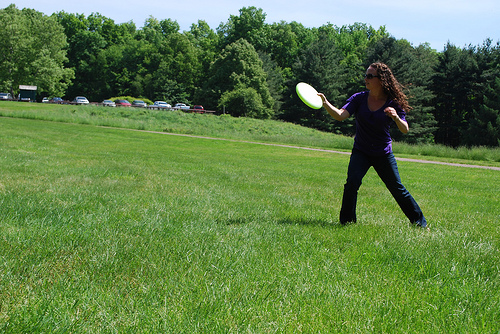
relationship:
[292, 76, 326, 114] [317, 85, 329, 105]
frisbee on hand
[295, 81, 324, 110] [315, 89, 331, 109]
frisbee on hand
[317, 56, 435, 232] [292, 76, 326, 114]
girl plays frisbee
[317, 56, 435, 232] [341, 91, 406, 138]
girl wears shirt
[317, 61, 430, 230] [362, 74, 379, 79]
girl wears glasses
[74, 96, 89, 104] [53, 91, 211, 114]
car in lot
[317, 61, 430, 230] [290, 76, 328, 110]
girl holds frisbee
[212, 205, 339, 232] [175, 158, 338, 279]
shadow on grass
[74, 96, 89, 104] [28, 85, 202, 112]
car in parking lot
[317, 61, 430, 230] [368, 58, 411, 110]
girl has hair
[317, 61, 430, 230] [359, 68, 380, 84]
girl has sunglasses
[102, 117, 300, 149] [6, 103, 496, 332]
pathway in park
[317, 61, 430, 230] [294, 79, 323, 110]
girl playing frisbee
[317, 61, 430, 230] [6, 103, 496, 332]
girl in park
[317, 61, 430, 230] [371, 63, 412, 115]
girl has hair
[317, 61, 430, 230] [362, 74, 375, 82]
girl wearing glasses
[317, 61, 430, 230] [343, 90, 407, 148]
girl has on shirt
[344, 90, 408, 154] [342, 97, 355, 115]
shirt has short sleeve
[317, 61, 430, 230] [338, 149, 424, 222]
girl has on pants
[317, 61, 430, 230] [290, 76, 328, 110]
girl holding frisbee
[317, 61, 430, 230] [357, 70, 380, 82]
girl wearing sunglasses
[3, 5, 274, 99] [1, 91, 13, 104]
tree behind car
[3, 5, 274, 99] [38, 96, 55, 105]
tree behind car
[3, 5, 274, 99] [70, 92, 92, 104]
tree behind car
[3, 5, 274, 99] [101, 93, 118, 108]
tree behind car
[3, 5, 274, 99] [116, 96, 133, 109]
tree behind car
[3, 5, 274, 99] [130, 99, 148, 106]
tree behind car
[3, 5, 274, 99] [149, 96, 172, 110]
tree behind car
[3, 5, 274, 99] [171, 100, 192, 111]
tree behind car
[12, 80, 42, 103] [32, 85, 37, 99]
building has side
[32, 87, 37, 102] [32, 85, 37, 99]
wall on side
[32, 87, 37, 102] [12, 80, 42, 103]
wall on building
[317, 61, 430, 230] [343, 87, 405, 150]
girl wearing shirt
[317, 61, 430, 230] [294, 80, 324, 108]
girl holding frisbee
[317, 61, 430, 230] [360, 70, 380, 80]
girl wearing sunglasses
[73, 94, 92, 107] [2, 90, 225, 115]
car parked in lot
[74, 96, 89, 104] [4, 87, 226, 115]
car parked in lot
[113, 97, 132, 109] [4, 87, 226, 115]
car parked in lot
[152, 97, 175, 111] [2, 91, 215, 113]
car parked in lot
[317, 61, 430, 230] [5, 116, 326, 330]
girl standing in grass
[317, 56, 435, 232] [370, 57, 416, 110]
girl has hair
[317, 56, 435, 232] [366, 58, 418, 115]
girl has hair